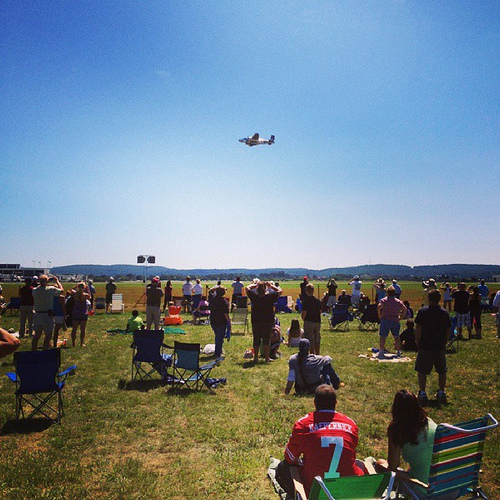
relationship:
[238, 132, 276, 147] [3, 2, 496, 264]
plane flying in sky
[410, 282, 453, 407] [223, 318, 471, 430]
person standing in field area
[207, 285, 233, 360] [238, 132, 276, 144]
person watching plane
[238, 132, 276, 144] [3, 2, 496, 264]
plane in sky